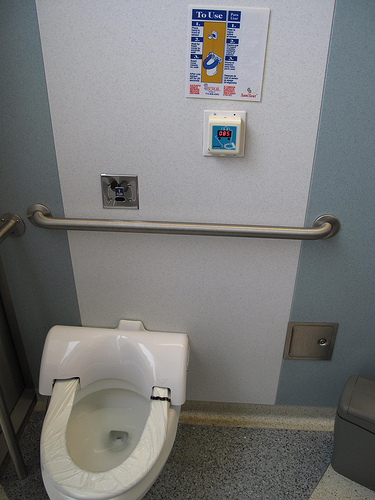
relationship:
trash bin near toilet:
[331, 371, 372, 491] [37, 319, 189, 499]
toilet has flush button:
[37, 319, 189, 499] [97, 174, 138, 211]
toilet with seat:
[37, 319, 189, 499] [41, 378, 168, 499]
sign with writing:
[184, 5, 272, 101] [187, 24, 242, 86]